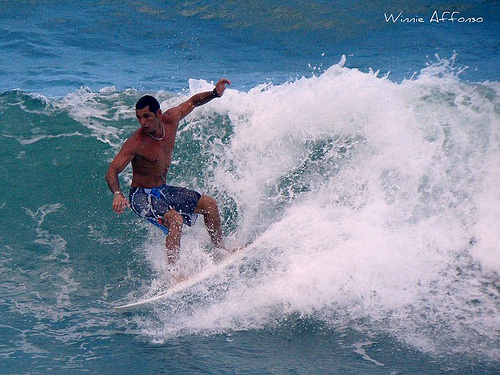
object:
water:
[0, 1, 500, 375]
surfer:
[105, 78, 231, 265]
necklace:
[146, 122, 165, 140]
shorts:
[129, 184, 202, 234]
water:
[268, 146, 368, 218]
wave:
[0, 53, 499, 375]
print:
[382, 10, 482, 24]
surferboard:
[111, 246, 251, 312]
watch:
[114, 191, 122, 195]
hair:
[136, 95, 160, 117]